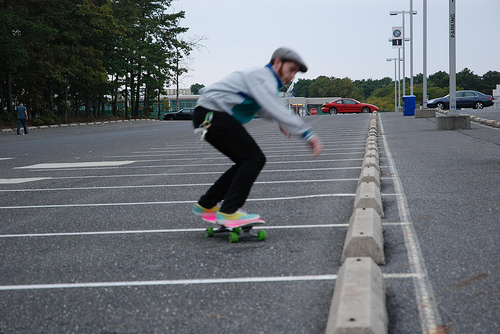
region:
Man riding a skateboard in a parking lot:
[188, 44, 328, 246]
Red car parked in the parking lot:
[319, 93, 382, 118]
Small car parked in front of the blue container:
[420, 85, 497, 113]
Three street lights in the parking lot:
[378, 6, 421, 113]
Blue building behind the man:
[63, 91, 346, 118]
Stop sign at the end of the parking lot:
[306, 103, 316, 114]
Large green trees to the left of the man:
[0, 1, 197, 131]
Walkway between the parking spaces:
[375, 104, 499, 332]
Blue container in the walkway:
[399, 91, 417, 118]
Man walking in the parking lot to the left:
[10, 99, 30, 139]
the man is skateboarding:
[158, 17, 316, 241]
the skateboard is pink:
[177, 189, 278, 239]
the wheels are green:
[218, 225, 270, 250]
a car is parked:
[308, 80, 383, 122]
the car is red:
[307, 77, 387, 128]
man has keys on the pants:
[187, 98, 231, 158]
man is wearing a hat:
[236, 35, 316, 94]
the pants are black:
[145, 83, 277, 219]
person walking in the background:
[1, 84, 68, 159]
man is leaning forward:
[166, 33, 345, 209]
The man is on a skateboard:
[189, 43, 324, 243]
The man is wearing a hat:
[269, 42, 306, 72]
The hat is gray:
[272, 47, 321, 69]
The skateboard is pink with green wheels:
[190, 205, 271, 245]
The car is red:
[321, 94, 378, 116]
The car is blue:
[426, 88, 498, 115]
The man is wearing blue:
[8, 96, 30, 139]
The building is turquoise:
[100, 73, 211, 120]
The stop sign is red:
[306, 105, 316, 117]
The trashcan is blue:
[398, 92, 420, 114]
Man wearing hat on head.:
[265, 43, 329, 93]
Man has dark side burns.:
[272, 53, 289, 80]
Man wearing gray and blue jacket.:
[220, 65, 274, 109]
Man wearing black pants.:
[194, 118, 249, 180]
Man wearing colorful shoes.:
[186, 178, 264, 250]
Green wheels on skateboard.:
[204, 222, 291, 262]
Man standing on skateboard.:
[154, 110, 270, 250]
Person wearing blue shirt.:
[16, 103, 33, 119]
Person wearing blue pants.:
[13, 116, 49, 144]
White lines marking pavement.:
[63, 123, 228, 315]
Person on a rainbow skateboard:
[185, 168, 296, 293]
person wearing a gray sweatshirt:
[180, 44, 282, 139]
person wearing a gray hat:
[253, 35, 305, 83]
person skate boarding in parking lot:
[206, 59, 291, 241]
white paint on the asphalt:
[29, 133, 174, 300]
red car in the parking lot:
[326, 87, 373, 122]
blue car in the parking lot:
[415, 80, 480, 108]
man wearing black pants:
[194, 101, 262, 203]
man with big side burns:
[271, 58, 293, 82]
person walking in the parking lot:
[10, 99, 45, 136]